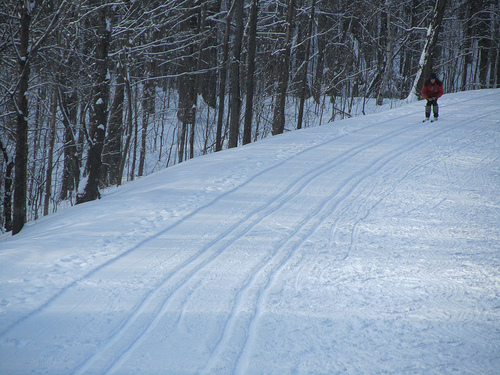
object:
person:
[422, 73, 444, 124]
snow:
[48, 225, 500, 375]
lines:
[71, 187, 354, 375]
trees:
[2, 0, 498, 239]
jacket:
[421, 78, 443, 98]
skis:
[423, 117, 439, 123]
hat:
[429, 73, 437, 80]